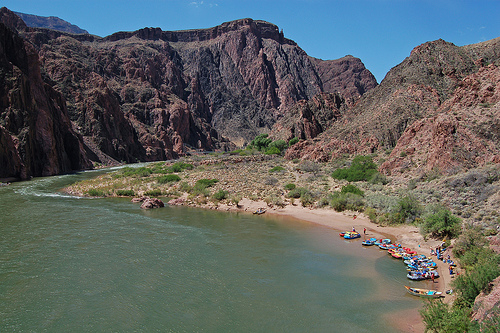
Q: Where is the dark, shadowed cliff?
A: At the left side.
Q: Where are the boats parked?
A: At the beach.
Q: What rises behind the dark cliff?
A: Another cliff.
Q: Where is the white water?
A: Where the river meets the beach.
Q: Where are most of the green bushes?
A: At the shoreline.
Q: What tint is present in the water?
A: Green.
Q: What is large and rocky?
A: A mountain.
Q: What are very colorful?
A: The boats.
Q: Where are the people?
A: On the sand.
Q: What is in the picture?
A: Boats.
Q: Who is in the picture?
A: People.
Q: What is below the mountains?
A: A river.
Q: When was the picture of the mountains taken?
A: Daytime.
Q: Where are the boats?
A: The river bank.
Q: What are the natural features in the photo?
A: Mountains.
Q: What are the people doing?
A: Standing.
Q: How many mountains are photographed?
A: Two.